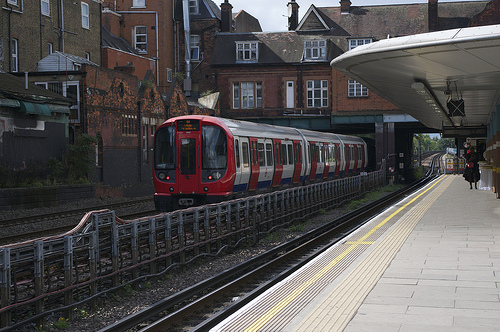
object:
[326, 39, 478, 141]
roof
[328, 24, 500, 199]
waiting area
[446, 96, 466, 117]
sign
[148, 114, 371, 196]
train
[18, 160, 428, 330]
tracks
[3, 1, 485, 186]
buildings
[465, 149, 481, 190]
person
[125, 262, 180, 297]
gravel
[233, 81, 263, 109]
window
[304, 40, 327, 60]
window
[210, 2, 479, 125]
building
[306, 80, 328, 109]
window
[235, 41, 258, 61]
window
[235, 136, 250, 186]
door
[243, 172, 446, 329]
line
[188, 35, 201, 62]
window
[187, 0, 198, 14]
window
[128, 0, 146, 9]
window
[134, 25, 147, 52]
window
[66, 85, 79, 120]
window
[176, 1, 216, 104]
building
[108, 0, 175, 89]
building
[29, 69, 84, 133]
building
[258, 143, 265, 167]
window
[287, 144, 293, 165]
window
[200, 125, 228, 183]
window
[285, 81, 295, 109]
door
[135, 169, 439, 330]
track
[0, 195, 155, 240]
track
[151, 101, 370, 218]
train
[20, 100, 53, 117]
canopy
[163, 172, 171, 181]
red light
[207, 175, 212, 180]
red light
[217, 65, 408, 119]
wall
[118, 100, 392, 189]
train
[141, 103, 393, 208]
train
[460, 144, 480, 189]
passenger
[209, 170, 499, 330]
platform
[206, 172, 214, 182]
headlight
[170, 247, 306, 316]
track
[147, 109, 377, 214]
train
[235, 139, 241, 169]
window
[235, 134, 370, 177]
doors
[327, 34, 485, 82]
overhang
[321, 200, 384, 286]
line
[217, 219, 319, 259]
tracks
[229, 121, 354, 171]
train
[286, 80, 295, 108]
window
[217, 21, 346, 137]
building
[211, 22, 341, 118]
building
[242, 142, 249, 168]
window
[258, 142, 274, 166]
window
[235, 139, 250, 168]
window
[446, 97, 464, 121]
t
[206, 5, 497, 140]
building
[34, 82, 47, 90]
window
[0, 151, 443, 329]
train tracks